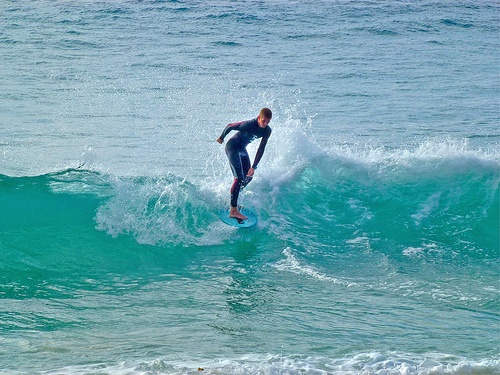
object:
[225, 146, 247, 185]
thigh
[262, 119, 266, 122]
eye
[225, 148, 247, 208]
leg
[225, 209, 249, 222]
feet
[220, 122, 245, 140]
arm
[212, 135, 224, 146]
hand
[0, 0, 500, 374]
water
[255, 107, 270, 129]
head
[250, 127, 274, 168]
arm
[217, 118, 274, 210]
wet suit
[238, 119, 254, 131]
shoulder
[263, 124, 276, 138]
shoulder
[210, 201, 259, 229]
board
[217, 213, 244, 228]
edge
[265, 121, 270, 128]
nose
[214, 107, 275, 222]
man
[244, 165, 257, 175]
hand